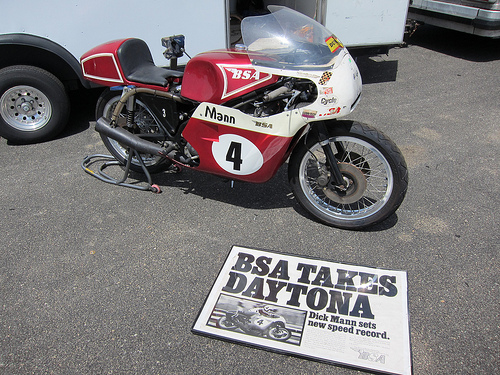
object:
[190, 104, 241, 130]
decal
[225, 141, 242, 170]
4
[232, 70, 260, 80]
bsa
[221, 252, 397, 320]
headline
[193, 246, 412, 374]
page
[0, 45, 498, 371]
ground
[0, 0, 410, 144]
trailer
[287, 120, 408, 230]
wheel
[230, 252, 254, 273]
letter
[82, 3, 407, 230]
bike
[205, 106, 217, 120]
letters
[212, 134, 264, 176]
circle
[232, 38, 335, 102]
windshield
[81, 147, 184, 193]
stand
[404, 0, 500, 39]
vehicle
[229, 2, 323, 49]
door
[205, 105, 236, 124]
mann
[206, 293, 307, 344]
picture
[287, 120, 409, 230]
tire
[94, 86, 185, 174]
tire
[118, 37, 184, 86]
seat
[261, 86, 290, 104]
handle bars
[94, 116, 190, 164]
tail pipe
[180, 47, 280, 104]
tank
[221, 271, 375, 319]
daytona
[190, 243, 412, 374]
frame